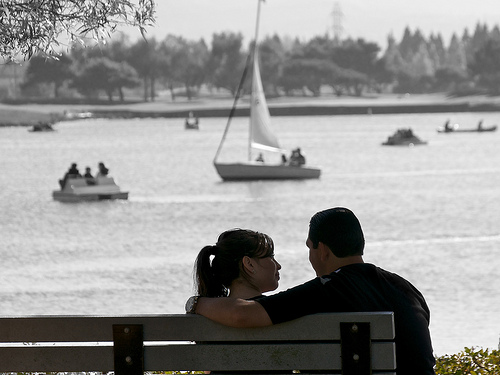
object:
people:
[57, 161, 86, 191]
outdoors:
[11, 32, 500, 99]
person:
[256, 151, 265, 163]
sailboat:
[211, 1, 322, 182]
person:
[280, 151, 288, 166]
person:
[291, 149, 298, 166]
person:
[298, 147, 308, 165]